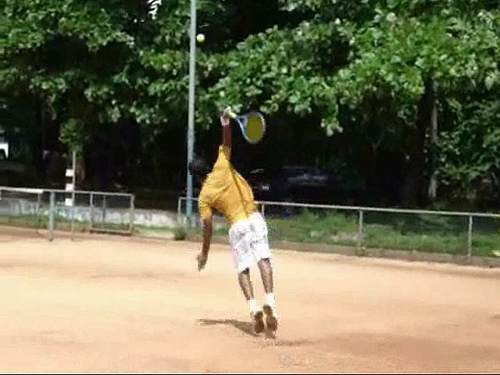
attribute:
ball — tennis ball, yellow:
[195, 32, 205, 42]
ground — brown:
[0, 230, 498, 372]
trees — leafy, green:
[14, 7, 479, 122]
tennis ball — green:
[194, 32, 208, 45]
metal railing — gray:
[2, 189, 499, 270]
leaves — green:
[363, 14, 491, 82]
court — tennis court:
[325, 317, 444, 361]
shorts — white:
[227, 212, 270, 272]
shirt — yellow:
[193, 151, 259, 222]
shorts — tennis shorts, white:
[218, 216, 327, 284]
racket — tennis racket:
[225, 113, 267, 150]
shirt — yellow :
[196, 142, 261, 232]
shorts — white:
[225, 211, 271, 268]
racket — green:
[217, 104, 272, 143]